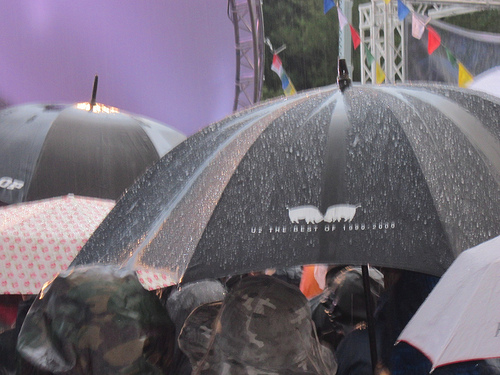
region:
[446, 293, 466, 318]
a white colored umbrella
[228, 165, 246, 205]
a black colored umbrella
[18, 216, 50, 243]
a pink and white umbrella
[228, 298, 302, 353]
a brown cup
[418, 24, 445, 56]
a red sheet on the line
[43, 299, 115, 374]
a green and brown cap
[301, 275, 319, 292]
an orange clothing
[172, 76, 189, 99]
a purple colored sky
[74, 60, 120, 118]
a shape stick on the umbrella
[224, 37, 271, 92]
a rail on the scene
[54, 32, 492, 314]
this is an umbrella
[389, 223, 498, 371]
this is an umbrella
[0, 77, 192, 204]
this is an umbrella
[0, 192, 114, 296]
this is an umbrella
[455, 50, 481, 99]
this is a piece of material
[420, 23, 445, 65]
this is a piece of material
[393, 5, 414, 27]
this is a piece of material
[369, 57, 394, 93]
this is a piece of material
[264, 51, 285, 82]
this is a piece of material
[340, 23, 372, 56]
this is a piece of material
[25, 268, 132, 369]
this is a person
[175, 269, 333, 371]
this is a person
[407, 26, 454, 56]
a piece of decorative material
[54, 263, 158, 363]
a piece of decorative material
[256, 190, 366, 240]
a trade mark and name on the umbrella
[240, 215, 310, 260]
this is a word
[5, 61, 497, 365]
many umbrellas in the rain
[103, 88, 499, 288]
largest umbrella in view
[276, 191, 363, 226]
image on the umbrella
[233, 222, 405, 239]
lettering on the umbrella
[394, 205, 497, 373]
umbrella with red trim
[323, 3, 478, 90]
string with colored flags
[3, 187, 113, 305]
umbrella with red patterns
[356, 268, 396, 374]
handle on the umbrella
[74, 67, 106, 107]
tall point on umbrella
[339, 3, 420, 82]
metal structure of stage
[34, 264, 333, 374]
people in camo hats under umbrella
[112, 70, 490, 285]
large black umbrella that is wet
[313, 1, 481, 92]
colorful flags hanging from the steel beams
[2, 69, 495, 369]
umbrellas being held by people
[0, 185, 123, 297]
white umbrella with pink patterns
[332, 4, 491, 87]
large white steel support beams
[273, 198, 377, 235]
image of two bulls on the large black umbrella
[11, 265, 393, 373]
people trying to stay dry under umbrellas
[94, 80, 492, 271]
umbrella covered in rain drops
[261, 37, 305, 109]
flags attached to the edge of the stage